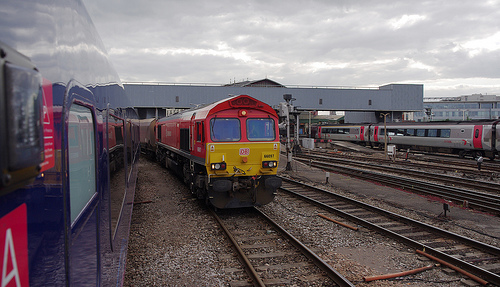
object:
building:
[119, 83, 424, 111]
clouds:
[145, 7, 469, 79]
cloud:
[113, 51, 252, 83]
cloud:
[92, 3, 257, 47]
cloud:
[274, 55, 435, 87]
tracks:
[275, 174, 500, 281]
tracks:
[292, 151, 500, 192]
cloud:
[107, 47, 497, 96]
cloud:
[92, 0, 499, 32]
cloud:
[113, 22, 499, 66]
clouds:
[248, 38, 369, 70]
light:
[212, 164, 215, 169]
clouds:
[334, 11, 488, 69]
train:
[141, 94, 282, 210]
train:
[0, 1, 134, 284]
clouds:
[433, 57, 494, 83]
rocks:
[296, 224, 315, 234]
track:
[208, 205, 355, 286]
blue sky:
[0, 0, 499, 97]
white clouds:
[135, 20, 231, 77]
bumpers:
[207, 172, 282, 208]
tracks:
[291, 157, 500, 216]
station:
[0, 0, 499, 286]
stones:
[154, 224, 230, 285]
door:
[473, 125, 482, 149]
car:
[368, 122, 495, 154]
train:
[319, 120, 500, 151]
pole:
[285, 105, 293, 170]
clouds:
[119, 49, 133, 77]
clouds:
[124, 55, 208, 81]